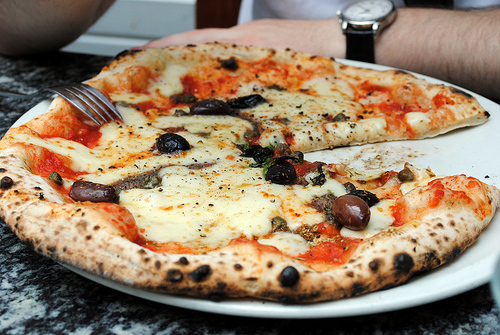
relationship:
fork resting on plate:
[1, 78, 123, 125] [53, 57, 499, 318]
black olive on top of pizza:
[156, 131, 189, 152] [2, 41, 499, 303]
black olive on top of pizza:
[264, 157, 297, 186] [2, 41, 499, 303]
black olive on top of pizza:
[332, 194, 371, 230] [2, 41, 499, 303]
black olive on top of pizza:
[69, 178, 114, 204] [2, 41, 499, 303]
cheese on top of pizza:
[21, 60, 438, 255] [2, 41, 499, 303]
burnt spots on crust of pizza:
[154, 241, 418, 301] [2, 41, 499, 303]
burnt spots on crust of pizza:
[1, 165, 46, 230] [2, 41, 499, 303]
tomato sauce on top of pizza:
[36, 57, 488, 270] [2, 41, 499, 303]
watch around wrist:
[334, 0, 398, 65] [303, 16, 346, 60]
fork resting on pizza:
[1, 78, 123, 125] [2, 41, 499, 303]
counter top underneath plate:
[1, 48, 498, 334] [53, 57, 499, 318]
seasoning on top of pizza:
[99, 87, 388, 249] [2, 41, 499, 303]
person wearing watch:
[1, 1, 499, 104] [334, 0, 398, 65]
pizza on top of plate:
[2, 41, 499, 303] [53, 57, 499, 318]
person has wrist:
[1, 1, 499, 104] [303, 16, 346, 60]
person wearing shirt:
[1, 1, 499, 104] [233, 1, 499, 33]